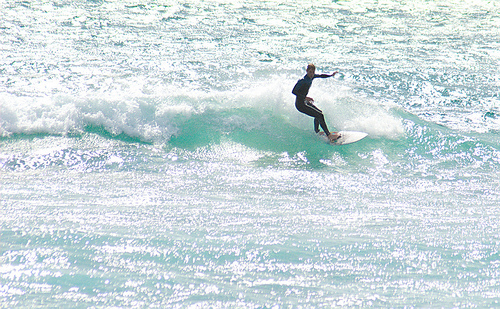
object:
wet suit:
[291, 73, 331, 136]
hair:
[306, 63, 316, 72]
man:
[291, 63, 341, 141]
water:
[0, 0, 499, 309]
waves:
[0, 79, 500, 186]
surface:
[0, 0, 499, 308]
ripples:
[0, 169, 499, 309]